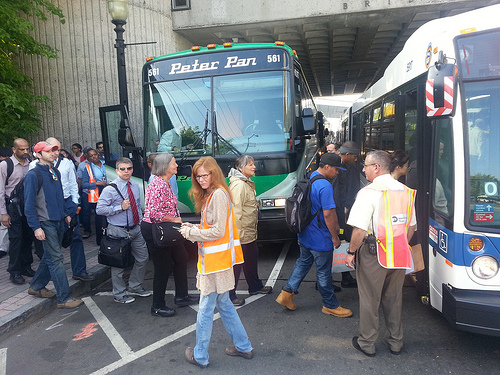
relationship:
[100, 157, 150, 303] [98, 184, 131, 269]
man holding briefcase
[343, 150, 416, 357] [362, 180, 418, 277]
man wearing red vest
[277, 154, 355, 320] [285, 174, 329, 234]
man wearing backpack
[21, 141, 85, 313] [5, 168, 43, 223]
everyone wearing bag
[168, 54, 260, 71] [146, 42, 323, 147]
name on bus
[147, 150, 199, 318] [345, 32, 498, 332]
lady walking towards bus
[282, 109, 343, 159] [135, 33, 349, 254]
mirror of bus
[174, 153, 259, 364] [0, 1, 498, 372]
lady in bus station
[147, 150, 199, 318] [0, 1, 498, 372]
lady in bus station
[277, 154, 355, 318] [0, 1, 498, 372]
man in bus station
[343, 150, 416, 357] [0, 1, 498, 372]
man in bus station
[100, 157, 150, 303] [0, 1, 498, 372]
man in bus station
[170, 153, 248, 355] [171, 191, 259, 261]
lady wearing jacket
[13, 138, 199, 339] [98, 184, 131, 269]
everyone carrying a briefcase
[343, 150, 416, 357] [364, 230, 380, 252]
man has a walkie talkie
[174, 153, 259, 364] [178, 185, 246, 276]
lady wearing jacket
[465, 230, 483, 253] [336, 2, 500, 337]
turn signal on blue/white bus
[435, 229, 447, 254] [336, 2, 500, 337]
handicap sticker on blue/white bus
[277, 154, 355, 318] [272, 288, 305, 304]
man wearing boot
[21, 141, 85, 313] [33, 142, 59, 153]
everyone wearing baseball cap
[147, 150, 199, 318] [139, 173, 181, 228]
lady wearing floral shirt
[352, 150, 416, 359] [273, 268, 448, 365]
man wearing boots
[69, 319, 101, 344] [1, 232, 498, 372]
red paint smeared on street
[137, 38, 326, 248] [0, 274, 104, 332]
bus parked at curb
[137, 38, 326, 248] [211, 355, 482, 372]
bus parked on street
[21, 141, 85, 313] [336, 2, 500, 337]
everyone boarding blue/white bus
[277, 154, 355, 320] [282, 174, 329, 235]
man wearing a backpack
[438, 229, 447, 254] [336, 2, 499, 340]
handicap sticker attached to blue/white bus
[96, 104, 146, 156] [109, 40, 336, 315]
door attached to bus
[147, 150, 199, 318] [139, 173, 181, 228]
lady wearing a floral shirt